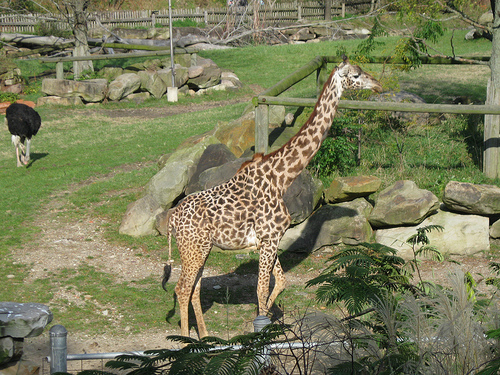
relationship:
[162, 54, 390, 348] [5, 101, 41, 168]
giraffe near animals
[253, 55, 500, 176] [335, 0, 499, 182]
railing around tree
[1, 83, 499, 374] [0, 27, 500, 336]
dirt path on grass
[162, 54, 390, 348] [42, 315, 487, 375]
giraffe near fence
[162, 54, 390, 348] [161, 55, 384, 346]
giraffe has markings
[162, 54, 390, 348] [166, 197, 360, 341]
giraffe has a shadow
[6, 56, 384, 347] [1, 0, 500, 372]
animals in enclosure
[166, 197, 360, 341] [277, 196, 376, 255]
shadow on rock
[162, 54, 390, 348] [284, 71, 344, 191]
giraffe has a long neck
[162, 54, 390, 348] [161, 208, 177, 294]
giraffe has a tail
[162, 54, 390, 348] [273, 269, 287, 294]
giraffe has a bent knee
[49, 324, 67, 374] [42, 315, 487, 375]
post on fence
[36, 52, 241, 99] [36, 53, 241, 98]
pile or large rocks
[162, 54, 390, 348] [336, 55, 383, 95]
giraffe has a head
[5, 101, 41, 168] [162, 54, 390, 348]
animals standing near giraffe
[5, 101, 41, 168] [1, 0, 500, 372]
animals in enclosure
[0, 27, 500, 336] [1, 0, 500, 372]
grass in enclosure